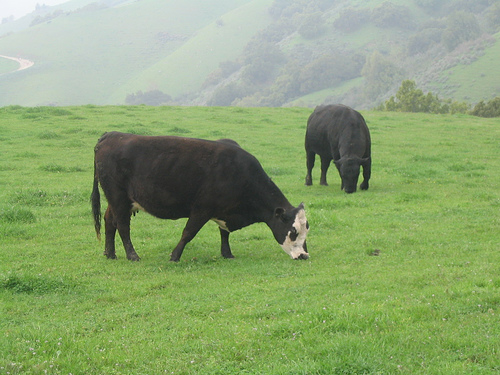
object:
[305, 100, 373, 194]
cow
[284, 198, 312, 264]
face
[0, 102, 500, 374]
grass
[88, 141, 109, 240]
tail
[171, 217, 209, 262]
legs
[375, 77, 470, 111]
trees